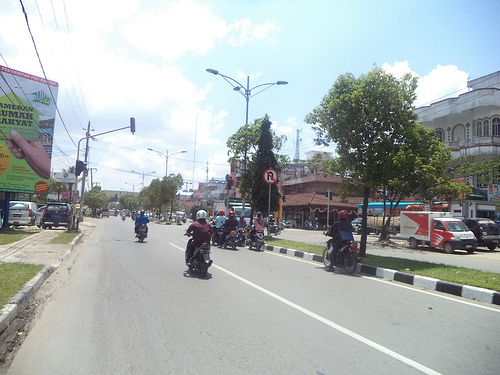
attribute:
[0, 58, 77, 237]
billboard — large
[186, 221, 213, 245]
shirt — burgundry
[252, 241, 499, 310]
border — black, white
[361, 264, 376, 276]
paint — black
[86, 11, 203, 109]
clouds — white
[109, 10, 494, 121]
sky — blue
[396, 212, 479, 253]
red/white truck — red, white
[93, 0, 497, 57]
sky — blue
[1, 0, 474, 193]
clouds — white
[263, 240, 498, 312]
sidewalk — black, white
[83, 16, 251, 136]
clouds — white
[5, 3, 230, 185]
wires — elevated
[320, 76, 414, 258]
tree — tall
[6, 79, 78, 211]
billboard — large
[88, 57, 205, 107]
sky — blue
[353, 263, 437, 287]
paint — white, black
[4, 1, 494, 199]
sky — blue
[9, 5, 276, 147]
clouds — white